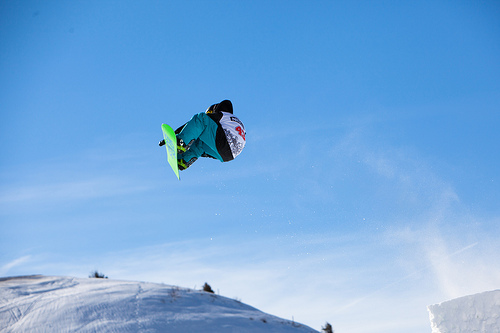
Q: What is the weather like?
A: It is clear.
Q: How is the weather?
A: It is clear.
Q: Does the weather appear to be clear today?
A: Yes, it is clear.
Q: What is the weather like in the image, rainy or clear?
A: It is clear.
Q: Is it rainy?
A: No, it is clear.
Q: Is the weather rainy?
A: No, it is clear.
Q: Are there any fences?
A: No, there are no fences.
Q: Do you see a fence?
A: No, there are no fences.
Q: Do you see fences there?
A: No, there are no fences.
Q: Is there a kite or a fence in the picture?
A: No, there are no fences or kites.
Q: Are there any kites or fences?
A: No, there are no fences or kites.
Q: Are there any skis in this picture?
A: No, there are no skis.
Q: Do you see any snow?
A: Yes, there is snow.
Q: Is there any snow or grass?
A: Yes, there is snow.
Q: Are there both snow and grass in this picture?
A: No, there is snow but no grass.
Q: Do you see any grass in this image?
A: No, there is no grass.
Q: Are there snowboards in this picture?
A: Yes, there is a snowboard.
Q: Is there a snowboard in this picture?
A: Yes, there is a snowboard.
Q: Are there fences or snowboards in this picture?
A: Yes, there is a snowboard.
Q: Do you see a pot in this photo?
A: No, there are no pots.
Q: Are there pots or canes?
A: No, there are no pots or canes.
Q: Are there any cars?
A: No, there are no cars.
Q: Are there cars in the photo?
A: No, there are no cars.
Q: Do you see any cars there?
A: No, there are no cars.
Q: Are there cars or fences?
A: No, there are no cars or fences.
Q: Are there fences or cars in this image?
A: No, there are no cars or fences.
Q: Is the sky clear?
A: Yes, the sky is clear.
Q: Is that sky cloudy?
A: No, the sky is clear.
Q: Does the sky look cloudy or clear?
A: The sky is clear.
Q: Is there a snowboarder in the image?
A: Yes, there is a snowboarder.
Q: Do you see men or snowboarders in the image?
A: Yes, there is a snowboarder.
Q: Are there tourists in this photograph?
A: No, there are no tourists.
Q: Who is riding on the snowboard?
A: The snowboarder is riding on the snowboard.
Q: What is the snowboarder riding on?
A: The snowboarder is riding on the snowboard.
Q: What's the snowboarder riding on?
A: The snowboarder is riding on the snowboard.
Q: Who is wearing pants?
A: The snowboarder is wearing pants.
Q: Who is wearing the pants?
A: The snowboarder is wearing pants.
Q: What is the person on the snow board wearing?
A: The snowboarder is wearing pants.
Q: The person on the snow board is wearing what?
A: The snowboarder is wearing pants.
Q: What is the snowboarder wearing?
A: The snowboarder is wearing pants.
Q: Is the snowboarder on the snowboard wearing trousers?
A: Yes, the snowboarder is wearing trousers.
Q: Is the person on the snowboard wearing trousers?
A: Yes, the snowboarder is wearing trousers.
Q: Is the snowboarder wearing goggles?
A: No, the snowboarder is wearing trousers.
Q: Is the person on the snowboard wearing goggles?
A: No, the snowboarder is wearing trousers.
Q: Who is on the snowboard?
A: The snowboarder is on the snowboard.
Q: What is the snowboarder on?
A: The snowboarder is on the snowboard.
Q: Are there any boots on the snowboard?
A: No, there is a snowboarder on the snowboard.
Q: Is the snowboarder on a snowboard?
A: Yes, the snowboarder is on a snowboard.